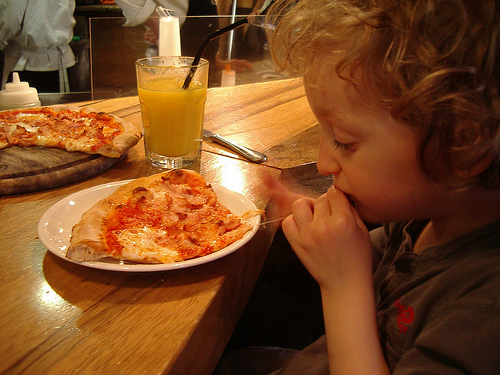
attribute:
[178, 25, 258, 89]
straw — black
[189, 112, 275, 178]
knife — silver, metal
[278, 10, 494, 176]
hair — curly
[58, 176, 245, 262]
pizza — half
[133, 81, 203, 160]
orange — juice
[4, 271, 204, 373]
table — brown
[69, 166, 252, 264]
pizza — yummy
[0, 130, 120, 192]
tray — wooden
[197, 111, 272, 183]
butter knife — metal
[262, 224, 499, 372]
shirt — brown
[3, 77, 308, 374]
counter — wood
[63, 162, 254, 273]
kittens face — cheese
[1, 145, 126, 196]
board — wooden, serving